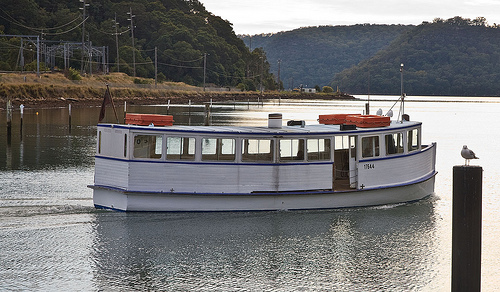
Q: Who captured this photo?
A: A photographer.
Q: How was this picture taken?
A: Camera.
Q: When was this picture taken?
A: Daytime.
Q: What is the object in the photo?
A: A ferry.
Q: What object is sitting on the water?
A: A boat.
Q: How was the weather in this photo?
A: Sunny.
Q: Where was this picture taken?
A: On the lake.